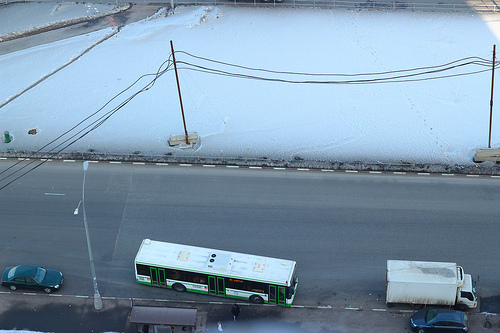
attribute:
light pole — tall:
[71, 157, 106, 312]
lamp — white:
[77, 166, 97, 306]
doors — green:
[143, 260, 175, 290]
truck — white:
[345, 233, 499, 316]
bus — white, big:
[133, 231, 302, 307]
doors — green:
[207, 277, 229, 298]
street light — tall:
[81, 156, 104, 311]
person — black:
[229, 302, 241, 324]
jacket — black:
[230, 307, 240, 318]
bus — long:
[129, 233, 305, 315]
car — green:
[4, 262, 66, 293]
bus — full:
[127, 222, 309, 310]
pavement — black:
[2, 156, 499, 331]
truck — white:
[370, 248, 487, 315]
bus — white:
[143, 233, 313, 298]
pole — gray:
[80, 159, 102, 312]